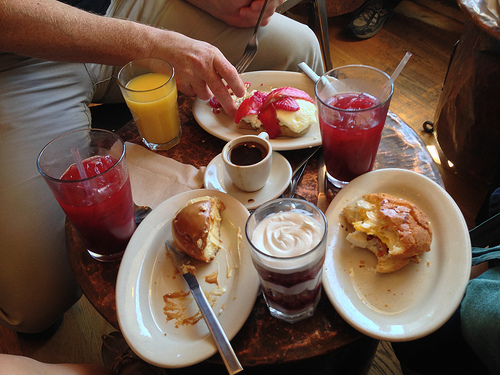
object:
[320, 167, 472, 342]
plate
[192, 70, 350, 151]
plate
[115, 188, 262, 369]
plate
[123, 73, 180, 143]
juice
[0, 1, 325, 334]
pants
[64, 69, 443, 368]
table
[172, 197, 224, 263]
doughnut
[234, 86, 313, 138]
strawberries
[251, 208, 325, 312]
milkshake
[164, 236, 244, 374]
knife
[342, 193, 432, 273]
sandwich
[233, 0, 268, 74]
fork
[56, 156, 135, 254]
juice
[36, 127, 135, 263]
glass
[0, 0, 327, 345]
man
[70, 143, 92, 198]
straw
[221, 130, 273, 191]
cup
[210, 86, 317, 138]
shortcake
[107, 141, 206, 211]
napkin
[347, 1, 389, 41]
shoe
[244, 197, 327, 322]
glass